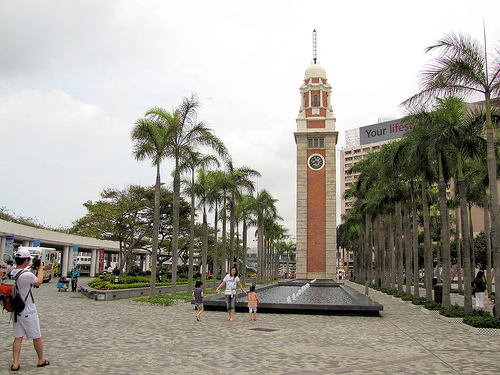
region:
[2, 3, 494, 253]
cloud cover in sky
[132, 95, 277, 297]
leaves of palm trees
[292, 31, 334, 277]
clocks on front of tower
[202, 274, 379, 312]
water in recatngle pool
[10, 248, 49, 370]
man with camera in hand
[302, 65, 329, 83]
white dome on tower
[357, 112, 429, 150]
words on gray sign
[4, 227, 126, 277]
columns under curved structure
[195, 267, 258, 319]
woman and two children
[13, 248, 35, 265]
white hat on head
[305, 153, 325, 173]
A clock on the tower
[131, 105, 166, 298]
A very tall palm tree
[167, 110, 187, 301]
The second palm tree in a row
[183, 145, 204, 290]
The third palm tree in the row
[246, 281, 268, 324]
A child walking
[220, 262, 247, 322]
A mother by the fountain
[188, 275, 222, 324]
A child by the mother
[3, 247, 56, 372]
A man taking a picture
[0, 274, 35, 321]
A red and grey backpack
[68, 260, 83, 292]
A person wearing a blue shirt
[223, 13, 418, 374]
a tall building at the end of the water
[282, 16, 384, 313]
a tall building with a clock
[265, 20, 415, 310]
a tall building with an outside clock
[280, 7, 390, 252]
a tall building with a large clock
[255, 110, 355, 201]
a clock to tell time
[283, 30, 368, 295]
a building with a clock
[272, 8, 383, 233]
a building with a large clock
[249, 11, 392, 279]
a building with an outside clock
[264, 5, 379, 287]
a building with a point at the top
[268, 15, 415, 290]
a clock to tell time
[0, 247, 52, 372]
Man with red and gray backpack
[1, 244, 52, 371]
Man wearing white baseball cap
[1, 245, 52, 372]
Man preparing to take photograph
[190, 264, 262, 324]
Woman with two children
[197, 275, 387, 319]
String of small fountains down middle of pool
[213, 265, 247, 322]
Woman wearing white shirt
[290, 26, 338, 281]
Red and beige stone clock tower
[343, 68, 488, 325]
Row of palm trees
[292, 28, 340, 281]
Antennae on top of clock tower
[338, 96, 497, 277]
Gray sign on top of builiding behind trees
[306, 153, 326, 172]
black faced clock on building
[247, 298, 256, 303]
pink shirt on little girl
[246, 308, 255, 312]
white shorts on girl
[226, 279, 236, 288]
white shirt on woman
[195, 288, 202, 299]
purple shirt on little girl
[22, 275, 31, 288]
grey shirt on man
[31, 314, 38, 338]
white shorts on man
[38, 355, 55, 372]
black sandals on man's foot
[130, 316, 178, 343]
checkered pattern on ground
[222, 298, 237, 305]
woman wearing blue jean capris